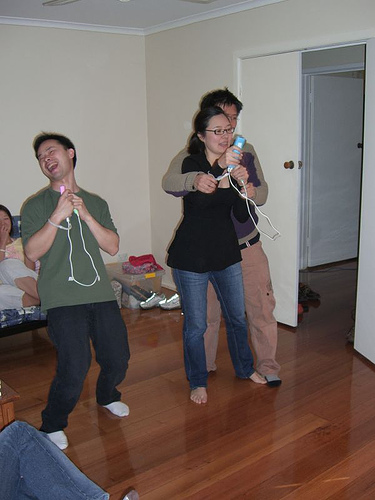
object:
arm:
[67, 192, 121, 256]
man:
[19, 133, 131, 449]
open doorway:
[295, 39, 373, 170]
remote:
[229, 136, 247, 172]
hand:
[219, 145, 243, 169]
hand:
[230, 163, 250, 185]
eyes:
[50, 148, 54, 154]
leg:
[214, 262, 253, 377]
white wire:
[232, 185, 287, 250]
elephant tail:
[139, 292, 165, 310]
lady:
[164, 104, 269, 405]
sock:
[123, 489, 139, 499]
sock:
[101, 401, 129, 417]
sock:
[46, 430, 67, 448]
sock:
[262, 368, 281, 386]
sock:
[207, 371, 210, 374]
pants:
[203, 240, 280, 370]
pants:
[38, 300, 130, 433]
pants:
[0, 420, 108, 499]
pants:
[0, 258, 38, 310]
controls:
[227, 135, 247, 175]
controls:
[59, 184, 79, 224]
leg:
[37, 305, 90, 432]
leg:
[172, 263, 209, 389]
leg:
[237, 238, 292, 374]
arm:
[19, 188, 73, 265]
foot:
[97, 396, 130, 418]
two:
[158, 92, 297, 412]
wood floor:
[159, 410, 352, 474]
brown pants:
[205, 234, 282, 375]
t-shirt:
[20, 187, 117, 311]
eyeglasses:
[199, 127, 236, 138]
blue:
[186, 285, 204, 361]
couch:
[0, 214, 55, 339]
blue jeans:
[172, 260, 256, 390]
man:
[161, 87, 282, 390]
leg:
[202, 276, 218, 372]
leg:
[83, 301, 132, 408]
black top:
[164, 148, 252, 274]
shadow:
[83, 401, 153, 499]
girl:
[0, 197, 41, 313]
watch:
[0, 245, 8, 254]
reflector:
[134, 288, 157, 309]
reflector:
[154, 290, 175, 307]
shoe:
[157, 286, 180, 313]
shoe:
[140, 288, 169, 311]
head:
[32, 129, 77, 182]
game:
[215, 132, 293, 247]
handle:
[283, 160, 294, 171]